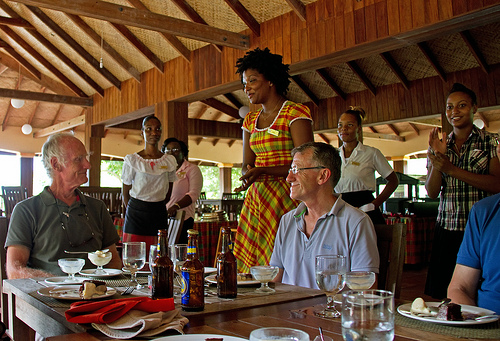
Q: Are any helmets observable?
A: No, there are no helmets.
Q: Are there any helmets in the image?
A: No, there are no helmets.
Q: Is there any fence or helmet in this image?
A: No, there are no helmets or fences.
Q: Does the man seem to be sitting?
A: Yes, the man is sitting.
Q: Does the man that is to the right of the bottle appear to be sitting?
A: Yes, the man is sitting.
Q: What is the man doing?
A: The man is sitting.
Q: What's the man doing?
A: The man is sitting.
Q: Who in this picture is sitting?
A: The man is sitting.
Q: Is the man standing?
A: No, the man is sitting.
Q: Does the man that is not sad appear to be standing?
A: No, the man is sitting.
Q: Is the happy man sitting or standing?
A: The man is sitting.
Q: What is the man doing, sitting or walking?
A: The man is sitting.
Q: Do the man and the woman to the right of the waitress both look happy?
A: Yes, both the man and the woman are happy.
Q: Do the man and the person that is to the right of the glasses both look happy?
A: Yes, both the man and the woman are happy.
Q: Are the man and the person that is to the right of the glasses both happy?
A: Yes, both the man and the woman are happy.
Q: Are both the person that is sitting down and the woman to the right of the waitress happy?
A: Yes, both the man and the woman are happy.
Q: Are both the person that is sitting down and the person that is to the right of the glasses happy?
A: Yes, both the man and the woman are happy.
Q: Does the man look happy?
A: Yes, the man is happy.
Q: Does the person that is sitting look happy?
A: Yes, the man is happy.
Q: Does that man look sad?
A: No, the man is happy.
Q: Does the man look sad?
A: No, the man is happy.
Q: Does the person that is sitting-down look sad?
A: No, the man is happy.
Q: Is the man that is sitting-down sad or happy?
A: The man is happy.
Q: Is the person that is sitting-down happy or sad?
A: The man is happy.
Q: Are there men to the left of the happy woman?
A: Yes, there is a man to the left of the woman.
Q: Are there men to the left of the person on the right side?
A: Yes, there is a man to the left of the woman.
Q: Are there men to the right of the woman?
A: No, the man is to the left of the woman.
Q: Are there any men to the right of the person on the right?
A: No, the man is to the left of the woman.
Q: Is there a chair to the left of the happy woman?
A: No, there is a man to the left of the woman.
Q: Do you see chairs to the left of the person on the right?
A: No, there is a man to the left of the woman.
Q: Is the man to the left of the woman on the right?
A: Yes, the man is to the left of the woman.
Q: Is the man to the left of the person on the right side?
A: Yes, the man is to the left of the woman.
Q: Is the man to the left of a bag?
A: No, the man is to the left of the woman.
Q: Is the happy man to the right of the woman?
A: No, the man is to the left of the woman.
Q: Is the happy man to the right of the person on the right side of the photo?
A: No, the man is to the left of the woman.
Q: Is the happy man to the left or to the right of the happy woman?
A: The man is to the left of the woman.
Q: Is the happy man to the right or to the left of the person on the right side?
A: The man is to the left of the woman.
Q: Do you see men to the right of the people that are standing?
A: Yes, there is a man to the right of the people.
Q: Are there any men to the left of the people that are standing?
A: No, the man is to the right of the people.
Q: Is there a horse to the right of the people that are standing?
A: No, there is a man to the right of the people.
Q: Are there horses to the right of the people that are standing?
A: No, there is a man to the right of the people.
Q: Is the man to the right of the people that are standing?
A: Yes, the man is to the right of the people.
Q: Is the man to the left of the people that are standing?
A: No, the man is to the right of the people.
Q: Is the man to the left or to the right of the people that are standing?
A: The man is to the right of the people.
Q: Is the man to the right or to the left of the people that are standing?
A: The man is to the right of the people.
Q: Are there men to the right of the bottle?
A: Yes, there is a man to the right of the bottle.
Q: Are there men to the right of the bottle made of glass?
A: Yes, there is a man to the right of the bottle.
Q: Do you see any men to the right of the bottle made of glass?
A: Yes, there is a man to the right of the bottle.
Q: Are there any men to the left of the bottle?
A: No, the man is to the right of the bottle.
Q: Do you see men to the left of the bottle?
A: No, the man is to the right of the bottle.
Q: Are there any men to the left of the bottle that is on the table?
A: No, the man is to the right of the bottle.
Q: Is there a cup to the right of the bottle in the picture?
A: No, there is a man to the right of the bottle.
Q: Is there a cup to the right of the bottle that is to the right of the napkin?
A: No, there is a man to the right of the bottle.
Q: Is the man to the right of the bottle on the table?
A: Yes, the man is to the right of the bottle.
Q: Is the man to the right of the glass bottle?
A: Yes, the man is to the right of the bottle.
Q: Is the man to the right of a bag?
A: No, the man is to the right of the bottle.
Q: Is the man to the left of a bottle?
A: No, the man is to the right of a bottle.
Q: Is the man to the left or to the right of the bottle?
A: The man is to the right of the bottle.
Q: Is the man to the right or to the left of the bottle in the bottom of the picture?
A: The man is to the right of the bottle.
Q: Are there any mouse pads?
A: No, there are no mouse pads.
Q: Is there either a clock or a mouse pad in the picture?
A: No, there are no mouse pads or clocks.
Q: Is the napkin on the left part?
A: Yes, the napkin is on the left of the image.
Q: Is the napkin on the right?
A: No, the napkin is on the left of the image.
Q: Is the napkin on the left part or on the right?
A: The napkin is on the left of the image.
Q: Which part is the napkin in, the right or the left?
A: The napkin is on the left of the image.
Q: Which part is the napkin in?
A: The napkin is on the left of the image.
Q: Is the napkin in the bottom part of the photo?
A: Yes, the napkin is in the bottom of the image.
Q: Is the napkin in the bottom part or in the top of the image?
A: The napkin is in the bottom of the image.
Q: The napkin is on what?
A: The napkin is on the table.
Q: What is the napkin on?
A: The napkin is on the table.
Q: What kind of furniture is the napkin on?
A: The napkin is on the table.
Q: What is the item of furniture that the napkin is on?
A: The piece of furniture is a table.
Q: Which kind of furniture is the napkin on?
A: The napkin is on the table.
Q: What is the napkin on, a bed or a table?
A: The napkin is on a table.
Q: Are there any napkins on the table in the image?
A: Yes, there is a napkin on the table.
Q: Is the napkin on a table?
A: Yes, the napkin is on a table.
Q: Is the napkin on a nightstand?
A: No, the napkin is on a table.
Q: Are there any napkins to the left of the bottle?
A: Yes, there is a napkin to the left of the bottle.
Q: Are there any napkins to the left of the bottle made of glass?
A: Yes, there is a napkin to the left of the bottle.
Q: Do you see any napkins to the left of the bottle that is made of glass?
A: Yes, there is a napkin to the left of the bottle.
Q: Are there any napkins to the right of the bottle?
A: No, the napkin is to the left of the bottle.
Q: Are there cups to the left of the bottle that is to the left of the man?
A: No, there is a napkin to the left of the bottle.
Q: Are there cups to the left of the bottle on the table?
A: No, there is a napkin to the left of the bottle.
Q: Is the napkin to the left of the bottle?
A: Yes, the napkin is to the left of the bottle.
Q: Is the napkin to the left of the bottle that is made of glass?
A: Yes, the napkin is to the left of the bottle.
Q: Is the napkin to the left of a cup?
A: No, the napkin is to the left of the bottle.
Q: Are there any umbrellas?
A: No, there are no umbrellas.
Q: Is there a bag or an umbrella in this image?
A: No, there are no umbrellas or bags.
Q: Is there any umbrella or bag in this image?
A: No, there are no umbrellas or bags.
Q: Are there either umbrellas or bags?
A: No, there are no umbrellas or bags.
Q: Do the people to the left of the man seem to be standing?
A: Yes, the people are standing.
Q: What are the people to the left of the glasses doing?
A: The people are standing.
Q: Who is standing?
A: The people are standing.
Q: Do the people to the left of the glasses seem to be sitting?
A: No, the people are standing.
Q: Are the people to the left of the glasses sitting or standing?
A: The people are standing.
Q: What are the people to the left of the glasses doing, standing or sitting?
A: The people are standing.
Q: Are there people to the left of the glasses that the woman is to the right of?
A: Yes, there are people to the left of the glasses.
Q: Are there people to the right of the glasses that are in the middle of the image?
A: No, the people are to the left of the glasses.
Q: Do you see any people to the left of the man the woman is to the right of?
A: Yes, there are people to the left of the man.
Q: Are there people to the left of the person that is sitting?
A: Yes, there are people to the left of the man.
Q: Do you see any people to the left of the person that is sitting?
A: Yes, there are people to the left of the man.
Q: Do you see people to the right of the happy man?
A: No, the people are to the left of the man.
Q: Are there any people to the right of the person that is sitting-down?
A: No, the people are to the left of the man.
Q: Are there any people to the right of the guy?
A: Yes, there are people to the right of the guy.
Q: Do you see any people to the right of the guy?
A: Yes, there are people to the right of the guy.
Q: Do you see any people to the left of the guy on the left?
A: No, the people are to the right of the guy.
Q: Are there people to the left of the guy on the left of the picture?
A: No, the people are to the right of the guy.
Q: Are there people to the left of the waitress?
A: Yes, there are people to the left of the waitress.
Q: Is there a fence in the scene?
A: No, there are no fences.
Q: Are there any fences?
A: No, there are no fences.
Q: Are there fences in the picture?
A: No, there are no fences.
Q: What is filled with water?
A: The glass is filled with water.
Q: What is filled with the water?
A: The glass is filled with water.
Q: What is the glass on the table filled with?
A: The glass is filled with water.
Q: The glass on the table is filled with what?
A: The glass is filled with water.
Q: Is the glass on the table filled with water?
A: Yes, the glass is filled with water.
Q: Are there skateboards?
A: No, there are no skateboards.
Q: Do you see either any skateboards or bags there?
A: No, there are no skateboards or bags.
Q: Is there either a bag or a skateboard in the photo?
A: No, there are no skateboards or bags.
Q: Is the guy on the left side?
A: Yes, the guy is on the left of the image.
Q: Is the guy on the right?
A: No, the guy is on the left of the image.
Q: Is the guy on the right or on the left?
A: The guy is on the left of the image.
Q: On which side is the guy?
A: The guy is on the left of the image.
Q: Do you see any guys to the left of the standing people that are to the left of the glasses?
A: Yes, there is a guy to the left of the people.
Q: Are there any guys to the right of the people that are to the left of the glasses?
A: No, the guy is to the left of the people.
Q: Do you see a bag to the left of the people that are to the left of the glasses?
A: No, there is a guy to the left of the people.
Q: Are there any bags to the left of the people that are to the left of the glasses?
A: No, there is a guy to the left of the people.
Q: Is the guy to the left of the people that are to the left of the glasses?
A: Yes, the guy is to the left of the people.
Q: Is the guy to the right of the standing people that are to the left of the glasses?
A: No, the guy is to the left of the people.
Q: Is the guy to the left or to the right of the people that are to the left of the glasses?
A: The guy is to the left of the people.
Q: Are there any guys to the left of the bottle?
A: Yes, there is a guy to the left of the bottle.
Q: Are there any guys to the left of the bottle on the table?
A: Yes, there is a guy to the left of the bottle.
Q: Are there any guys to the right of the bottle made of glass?
A: No, the guy is to the left of the bottle.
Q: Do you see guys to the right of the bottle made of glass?
A: No, the guy is to the left of the bottle.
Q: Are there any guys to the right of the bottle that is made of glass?
A: No, the guy is to the left of the bottle.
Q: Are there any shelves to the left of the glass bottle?
A: No, there is a guy to the left of the bottle.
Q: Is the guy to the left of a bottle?
A: Yes, the guy is to the left of a bottle.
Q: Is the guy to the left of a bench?
A: No, the guy is to the left of a bottle.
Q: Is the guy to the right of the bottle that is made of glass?
A: No, the guy is to the left of the bottle.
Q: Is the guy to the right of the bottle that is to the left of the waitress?
A: No, the guy is to the left of the bottle.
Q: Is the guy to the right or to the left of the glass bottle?
A: The guy is to the left of the bottle.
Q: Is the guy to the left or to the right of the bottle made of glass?
A: The guy is to the left of the bottle.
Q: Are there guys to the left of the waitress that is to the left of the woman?
A: Yes, there is a guy to the left of the waitress.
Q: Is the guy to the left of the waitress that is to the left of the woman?
A: Yes, the guy is to the left of the waitress.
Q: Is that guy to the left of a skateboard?
A: No, the guy is to the left of the waitress.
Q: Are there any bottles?
A: Yes, there is a bottle.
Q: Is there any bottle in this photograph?
A: Yes, there is a bottle.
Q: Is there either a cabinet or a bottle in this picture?
A: Yes, there is a bottle.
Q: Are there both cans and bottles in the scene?
A: No, there is a bottle but no cans.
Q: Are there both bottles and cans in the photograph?
A: No, there is a bottle but no cans.